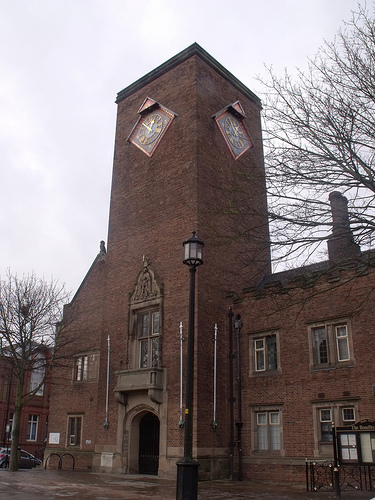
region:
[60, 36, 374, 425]
the building is brown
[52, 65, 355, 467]
the building is brown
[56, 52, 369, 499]
the building is brown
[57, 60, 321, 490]
the building is brown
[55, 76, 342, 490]
the building is brown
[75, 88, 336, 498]
the building is brown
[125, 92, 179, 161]
a diamond framing a clock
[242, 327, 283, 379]
a window cracked open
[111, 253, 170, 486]
an ornate entry way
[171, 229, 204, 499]
a tall street lamp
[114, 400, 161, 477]
a church door way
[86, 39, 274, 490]
a tall church tower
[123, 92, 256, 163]
clocks at the top of a church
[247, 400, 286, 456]
a window on a brick building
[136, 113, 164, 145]
an ornate analog clock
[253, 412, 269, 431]
a window on a building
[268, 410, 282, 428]
a window on a building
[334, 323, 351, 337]
a window on a building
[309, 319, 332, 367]
a window on a building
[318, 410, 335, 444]
a window on a building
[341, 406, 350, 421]
a window on a building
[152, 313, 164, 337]
a window on a building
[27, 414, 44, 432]
a window on a building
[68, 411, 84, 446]
a window on a building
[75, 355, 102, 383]
a window on a building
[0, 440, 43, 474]
The silver car that is parked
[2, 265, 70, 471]
The tree next to the car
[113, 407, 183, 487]
The gated entryway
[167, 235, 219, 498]
The street light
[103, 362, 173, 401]
The balcony above the entryway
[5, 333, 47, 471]
The building in the background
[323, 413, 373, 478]
The black sign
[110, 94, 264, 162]
There are two clocks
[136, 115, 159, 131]
The clock has gold hands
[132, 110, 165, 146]
The numbers are roman numerals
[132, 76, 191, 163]
a clock on a building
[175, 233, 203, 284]
a lgiht on a pole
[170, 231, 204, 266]
a light on a metal pole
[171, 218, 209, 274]
a pole with a light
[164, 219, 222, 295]
a metal pole with a light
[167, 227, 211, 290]
a street light on a pole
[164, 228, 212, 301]
a street light on a metal pole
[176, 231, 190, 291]
a poel with street light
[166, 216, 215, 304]
a metal pole on street light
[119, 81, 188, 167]
an outside clock on building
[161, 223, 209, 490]
the lamppost is black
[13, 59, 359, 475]
a church that is really big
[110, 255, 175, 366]
the main window of a church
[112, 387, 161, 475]
the front door of a church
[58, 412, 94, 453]
a small window of a church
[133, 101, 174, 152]
a clock of a church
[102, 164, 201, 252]
the main wall of a church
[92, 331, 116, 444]
a large pole of a church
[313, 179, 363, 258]
a large chimney of a church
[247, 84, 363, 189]
a tree without any of the leaves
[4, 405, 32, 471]
a log that is tall and skinny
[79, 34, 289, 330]
a tower on a building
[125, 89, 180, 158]
a clock on front a tower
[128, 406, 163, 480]
the door is color brown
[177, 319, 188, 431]
a pole on front a building